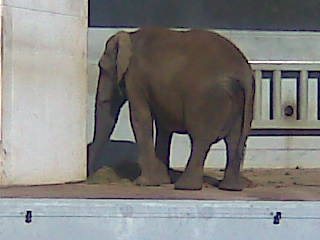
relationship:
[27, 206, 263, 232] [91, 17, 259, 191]
wall in front of elephant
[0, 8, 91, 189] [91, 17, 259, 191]
wall near elephant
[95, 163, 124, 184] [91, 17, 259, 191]
grass near elephant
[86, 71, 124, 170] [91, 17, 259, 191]
trunk of elephant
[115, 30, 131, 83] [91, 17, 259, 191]
ear of elephant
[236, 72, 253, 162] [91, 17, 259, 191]
tail of elephant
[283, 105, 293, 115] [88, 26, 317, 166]
hole in wall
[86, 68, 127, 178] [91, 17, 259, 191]
trunk on elephant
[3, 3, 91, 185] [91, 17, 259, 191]
wall by elephant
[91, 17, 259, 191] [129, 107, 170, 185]
elephant has leg